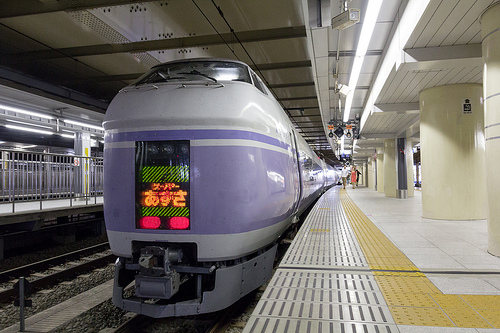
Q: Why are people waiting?
A: For the train.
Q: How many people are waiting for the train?
A: Three.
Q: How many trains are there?
A: One.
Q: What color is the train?
A: Blue and white.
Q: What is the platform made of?
A: Metal.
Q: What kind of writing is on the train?
A: Asian.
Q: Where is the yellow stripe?
A: Platform.